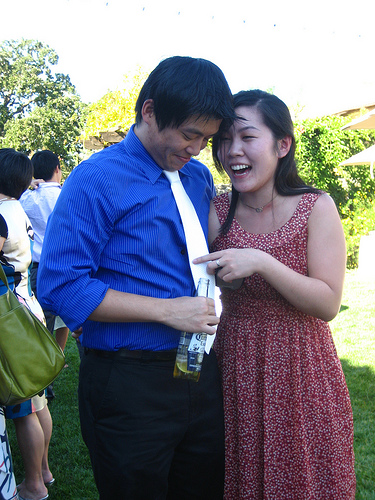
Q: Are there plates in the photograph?
A: No, there are no plates.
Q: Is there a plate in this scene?
A: No, there are no plates.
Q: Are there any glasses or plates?
A: No, there are no plates or glasses.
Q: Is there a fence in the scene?
A: No, there are no fences.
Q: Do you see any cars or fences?
A: No, there are no fences or cars.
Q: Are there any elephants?
A: No, there are no elephants.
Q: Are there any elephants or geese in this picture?
A: No, there are no elephants or geese.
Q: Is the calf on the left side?
A: Yes, the calf is on the left of the image.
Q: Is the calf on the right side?
A: No, the calf is on the left of the image.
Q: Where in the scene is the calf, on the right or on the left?
A: The calf is on the left of the image.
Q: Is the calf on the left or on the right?
A: The calf is on the left of the image.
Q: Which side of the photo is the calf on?
A: The calf is on the left of the image.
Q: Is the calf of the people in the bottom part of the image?
A: Yes, the calf is in the bottom of the image.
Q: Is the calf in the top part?
A: No, the calf is in the bottom of the image.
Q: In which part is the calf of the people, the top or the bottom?
A: The calf is in the bottom of the image.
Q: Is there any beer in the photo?
A: Yes, there is beer.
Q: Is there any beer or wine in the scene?
A: Yes, there is beer.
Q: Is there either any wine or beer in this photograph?
A: Yes, there is beer.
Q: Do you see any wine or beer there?
A: Yes, there is beer.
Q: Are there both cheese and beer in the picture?
A: No, there is beer but no cheese.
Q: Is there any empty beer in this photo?
A: Yes, there is empty beer.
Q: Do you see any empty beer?
A: Yes, there is empty beer.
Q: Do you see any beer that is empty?
A: Yes, there is empty beer.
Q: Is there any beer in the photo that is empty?
A: Yes, there is beer that is empty.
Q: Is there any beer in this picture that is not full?
A: Yes, there is empty beer.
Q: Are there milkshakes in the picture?
A: No, there are no milkshakes.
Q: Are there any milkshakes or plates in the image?
A: No, there are no milkshakes or plates.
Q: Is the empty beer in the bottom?
A: Yes, the beer is in the bottom of the image.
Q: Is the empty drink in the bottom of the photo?
A: Yes, the beer is in the bottom of the image.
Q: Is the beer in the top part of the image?
A: No, the beer is in the bottom of the image.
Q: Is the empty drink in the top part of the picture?
A: No, the beer is in the bottom of the image.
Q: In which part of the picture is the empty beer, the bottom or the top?
A: The beer is in the bottom of the image.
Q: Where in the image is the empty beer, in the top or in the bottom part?
A: The beer is in the bottom of the image.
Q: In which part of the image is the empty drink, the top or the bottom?
A: The beer is in the bottom of the image.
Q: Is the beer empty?
A: Yes, the beer is empty.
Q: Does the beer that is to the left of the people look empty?
A: Yes, the beer is empty.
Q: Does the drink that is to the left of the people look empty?
A: Yes, the beer is empty.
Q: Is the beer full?
A: No, the beer is empty.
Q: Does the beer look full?
A: No, the beer is empty.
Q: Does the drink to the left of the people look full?
A: No, the beer is empty.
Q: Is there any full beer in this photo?
A: No, there is beer but it is empty.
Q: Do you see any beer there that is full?
A: No, there is beer but it is empty.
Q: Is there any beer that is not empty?
A: No, there is beer but it is empty.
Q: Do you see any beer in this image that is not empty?
A: No, there is beer but it is empty.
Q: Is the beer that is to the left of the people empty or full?
A: The beer is empty.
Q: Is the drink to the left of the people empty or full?
A: The beer is empty.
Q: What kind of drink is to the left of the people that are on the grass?
A: The drink is beer.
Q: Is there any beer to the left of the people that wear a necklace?
A: Yes, there is beer to the left of the people.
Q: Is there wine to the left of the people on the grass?
A: No, there is beer to the left of the people.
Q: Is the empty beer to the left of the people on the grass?
A: Yes, the beer is to the left of the people.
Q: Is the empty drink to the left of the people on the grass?
A: Yes, the beer is to the left of the people.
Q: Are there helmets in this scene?
A: No, there are no helmets.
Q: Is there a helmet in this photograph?
A: No, there are no helmets.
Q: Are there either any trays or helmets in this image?
A: No, there are no helmets or trays.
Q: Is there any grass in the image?
A: Yes, there is grass.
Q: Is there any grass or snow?
A: Yes, there is grass.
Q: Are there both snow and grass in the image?
A: No, there is grass but no snow.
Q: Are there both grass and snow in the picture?
A: No, there is grass but no snow.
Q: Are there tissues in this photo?
A: No, there are no tissues.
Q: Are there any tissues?
A: No, there are no tissues.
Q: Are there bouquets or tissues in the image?
A: No, there are no tissues or bouquets.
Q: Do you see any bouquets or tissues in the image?
A: No, there are no tissues or bouquets.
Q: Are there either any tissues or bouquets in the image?
A: No, there are no tissues or bouquets.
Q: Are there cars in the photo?
A: No, there are no cars.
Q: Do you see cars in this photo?
A: No, there are no cars.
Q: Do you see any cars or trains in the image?
A: No, there are no cars or trains.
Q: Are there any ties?
A: Yes, there is a tie.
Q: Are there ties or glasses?
A: Yes, there is a tie.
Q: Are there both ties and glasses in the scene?
A: No, there is a tie but no glasses.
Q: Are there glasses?
A: No, there are no glasses.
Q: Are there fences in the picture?
A: No, there are no fences.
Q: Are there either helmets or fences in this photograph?
A: No, there are no fences or helmets.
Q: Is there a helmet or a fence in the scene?
A: No, there are no fences or helmets.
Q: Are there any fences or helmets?
A: No, there are no fences or helmets.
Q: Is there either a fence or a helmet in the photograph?
A: No, there are no fences or helmets.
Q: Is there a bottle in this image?
A: Yes, there is a bottle.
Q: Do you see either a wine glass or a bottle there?
A: Yes, there is a bottle.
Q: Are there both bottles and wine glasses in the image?
A: No, there is a bottle but no wine glasses.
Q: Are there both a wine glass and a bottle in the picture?
A: No, there is a bottle but no wine glasses.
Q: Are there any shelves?
A: No, there are no shelves.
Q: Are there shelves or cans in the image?
A: No, there are no shelves or cans.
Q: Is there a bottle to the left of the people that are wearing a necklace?
A: Yes, there is a bottle to the left of the people.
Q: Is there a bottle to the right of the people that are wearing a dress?
A: No, the bottle is to the left of the people.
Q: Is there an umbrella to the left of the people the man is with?
A: No, there is a bottle to the left of the people.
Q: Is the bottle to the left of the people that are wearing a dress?
A: Yes, the bottle is to the left of the people.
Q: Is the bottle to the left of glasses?
A: No, the bottle is to the left of the people.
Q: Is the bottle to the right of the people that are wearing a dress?
A: No, the bottle is to the left of the people.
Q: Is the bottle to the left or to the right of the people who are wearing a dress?
A: The bottle is to the left of the people.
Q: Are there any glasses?
A: No, there are no glasses.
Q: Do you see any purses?
A: Yes, there is a purse.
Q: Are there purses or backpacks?
A: Yes, there is a purse.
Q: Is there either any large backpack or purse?
A: Yes, there is a large purse.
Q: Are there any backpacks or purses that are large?
A: Yes, the purse is large.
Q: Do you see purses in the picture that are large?
A: Yes, there is a large purse.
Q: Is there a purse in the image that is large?
A: Yes, there is a purse that is large.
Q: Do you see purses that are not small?
A: Yes, there is a large purse.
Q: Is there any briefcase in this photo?
A: No, there are no briefcases.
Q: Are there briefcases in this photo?
A: No, there are no briefcases.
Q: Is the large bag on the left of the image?
A: Yes, the purse is on the left of the image.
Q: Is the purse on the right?
A: No, the purse is on the left of the image.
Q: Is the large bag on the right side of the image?
A: No, the purse is on the left of the image.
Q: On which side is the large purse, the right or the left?
A: The purse is on the left of the image.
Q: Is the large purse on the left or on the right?
A: The purse is on the left of the image.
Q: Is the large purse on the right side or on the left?
A: The purse is on the left of the image.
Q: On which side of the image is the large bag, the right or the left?
A: The purse is on the left of the image.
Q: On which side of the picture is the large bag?
A: The purse is on the left of the image.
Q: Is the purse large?
A: Yes, the purse is large.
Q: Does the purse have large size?
A: Yes, the purse is large.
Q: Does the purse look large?
A: Yes, the purse is large.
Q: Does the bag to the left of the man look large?
A: Yes, the purse is large.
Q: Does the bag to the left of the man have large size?
A: Yes, the purse is large.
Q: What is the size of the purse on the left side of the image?
A: The purse is large.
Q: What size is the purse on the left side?
A: The purse is large.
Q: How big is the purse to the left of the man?
A: The purse is large.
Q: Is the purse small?
A: No, the purse is large.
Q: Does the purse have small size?
A: No, the purse is large.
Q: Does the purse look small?
A: No, the purse is large.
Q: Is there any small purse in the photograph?
A: No, there is a purse but it is large.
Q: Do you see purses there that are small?
A: No, there is a purse but it is large.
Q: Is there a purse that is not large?
A: No, there is a purse but it is large.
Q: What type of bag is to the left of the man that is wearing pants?
A: The bag is a purse.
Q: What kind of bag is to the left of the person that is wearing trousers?
A: The bag is a purse.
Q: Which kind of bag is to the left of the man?
A: The bag is a purse.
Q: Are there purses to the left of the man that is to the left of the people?
A: Yes, there is a purse to the left of the man.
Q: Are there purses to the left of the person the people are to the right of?
A: Yes, there is a purse to the left of the man.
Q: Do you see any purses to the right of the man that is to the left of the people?
A: No, the purse is to the left of the man.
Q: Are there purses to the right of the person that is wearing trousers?
A: No, the purse is to the left of the man.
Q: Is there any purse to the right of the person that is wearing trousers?
A: No, the purse is to the left of the man.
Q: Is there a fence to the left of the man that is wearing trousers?
A: No, there is a purse to the left of the man.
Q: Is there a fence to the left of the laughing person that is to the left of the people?
A: No, there is a purse to the left of the man.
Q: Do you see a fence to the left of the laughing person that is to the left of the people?
A: No, there is a purse to the left of the man.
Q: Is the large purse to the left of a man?
A: Yes, the purse is to the left of a man.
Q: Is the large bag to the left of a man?
A: Yes, the purse is to the left of a man.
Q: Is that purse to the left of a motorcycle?
A: No, the purse is to the left of a man.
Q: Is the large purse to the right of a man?
A: No, the purse is to the left of a man.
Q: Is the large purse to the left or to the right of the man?
A: The purse is to the left of the man.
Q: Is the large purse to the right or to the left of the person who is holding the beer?
A: The purse is to the left of the man.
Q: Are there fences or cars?
A: No, there are no fences or cars.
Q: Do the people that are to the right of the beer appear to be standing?
A: Yes, the people are standing.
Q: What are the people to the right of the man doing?
A: The people are standing.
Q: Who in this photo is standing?
A: The people are standing.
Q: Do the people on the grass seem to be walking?
A: No, the people are standing.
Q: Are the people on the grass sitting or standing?
A: The people are standing.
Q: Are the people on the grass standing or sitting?
A: The people are standing.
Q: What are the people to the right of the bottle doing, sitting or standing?
A: The people are standing.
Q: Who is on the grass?
A: The people are on the grass.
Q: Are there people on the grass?
A: Yes, there are people on the grass.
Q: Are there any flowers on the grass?
A: No, there are people on the grass.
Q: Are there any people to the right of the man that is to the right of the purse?
A: Yes, there are people to the right of the man.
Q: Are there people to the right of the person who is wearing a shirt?
A: Yes, there are people to the right of the man.